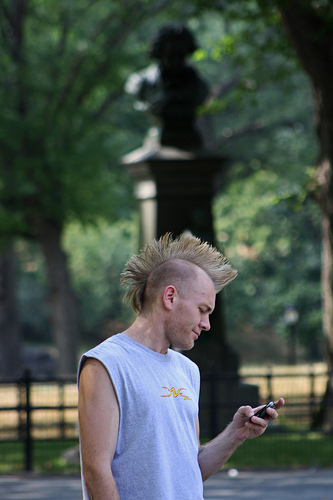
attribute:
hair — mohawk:
[134, 234, 231, 278]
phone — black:
[249, 400, 278, 424]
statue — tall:
[111, 13, 266, 431]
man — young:
[73, 232, 286, 498]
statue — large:
[119, 19, 226, 245]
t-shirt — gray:
[94, 337, 192, 498]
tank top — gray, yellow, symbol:
[76, 332, 203, 498]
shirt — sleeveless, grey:
[74, 338, 206, 499]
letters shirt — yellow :
[159, 384, 196, 409]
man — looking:
[99, 214, 212, 418]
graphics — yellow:
[153, 382, 194, 407]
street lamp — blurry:
[279, 304, 300, 365]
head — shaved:
[121, 230, 238, 352]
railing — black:
[1, 377, 332, 482]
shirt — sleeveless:
[54, 333, 219, 499]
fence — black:
[3, 370, 331, 463]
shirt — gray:
[69, 346, 238, 490]